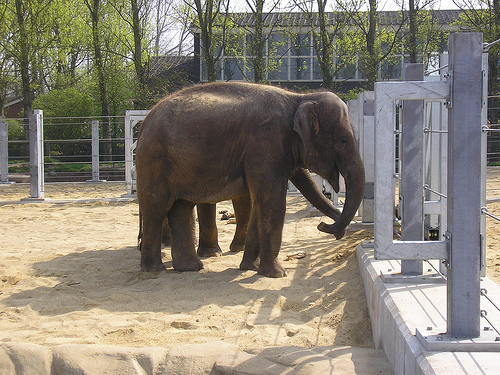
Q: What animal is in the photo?
A: Elephant.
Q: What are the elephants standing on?
A: Sand.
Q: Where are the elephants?
A: Enclosure.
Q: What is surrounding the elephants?
A: Fence.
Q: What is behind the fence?
A: Trees.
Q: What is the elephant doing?
A: Eating.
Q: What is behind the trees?
A: Building.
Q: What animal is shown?
A: An elephant.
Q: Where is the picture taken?
A: A zoo.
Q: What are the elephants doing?
A: Eating.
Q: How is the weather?
A: Sunny.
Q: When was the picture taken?
A: Afternoon.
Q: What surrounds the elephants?
A: Fencing.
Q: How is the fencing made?
A: Of metal.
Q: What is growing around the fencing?
A: Trees.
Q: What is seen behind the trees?
A: A building.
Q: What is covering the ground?
A: Sand.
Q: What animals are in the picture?
A: Elephants.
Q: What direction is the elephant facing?
A: To the right.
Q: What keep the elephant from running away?
A: A fence.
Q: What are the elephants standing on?
A: Sand.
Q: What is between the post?
A: Steel cables.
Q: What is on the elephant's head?
A: A trunk.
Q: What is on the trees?
A: Green leaves.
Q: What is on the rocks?
A: Shadows of the fence.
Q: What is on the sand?
A: Shadows of the elephants.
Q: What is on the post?
A: Bolts and cables.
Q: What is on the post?
A: Shadows.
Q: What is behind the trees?
A: A building.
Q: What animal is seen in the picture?
A: Elephant.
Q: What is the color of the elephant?
A: Grey.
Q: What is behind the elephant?
A: Trees and building.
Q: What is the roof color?
A: Black.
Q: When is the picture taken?
A: Daytime.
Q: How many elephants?
A: 2.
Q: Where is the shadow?
A: In the ground.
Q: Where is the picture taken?
A: At a game reserve.